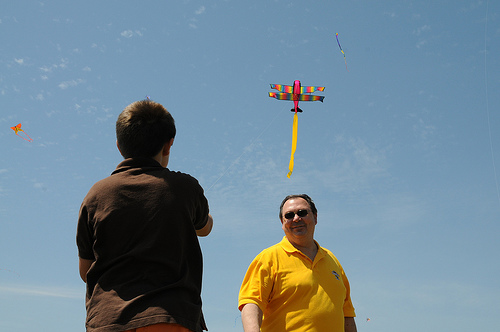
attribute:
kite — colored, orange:
[260, 71, 337, 183]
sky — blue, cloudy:
[0, 0, 499, 331]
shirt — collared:
[235, 237, 359, 330]